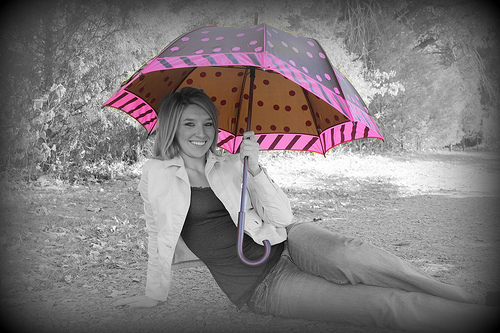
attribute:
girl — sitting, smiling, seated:
[128, 86, 499, 332]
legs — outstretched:
[247, 222, 498, 332]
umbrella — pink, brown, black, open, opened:
[99, 14, 386, 266]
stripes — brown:
[275, 132, 296, 149]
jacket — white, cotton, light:
[132, 148, 305, 291]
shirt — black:
[169, 157, 278, 309]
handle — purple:
[227, 209, 277, 269]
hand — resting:
[106, 293, 166, 309]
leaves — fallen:
[34, 202, 152, 300]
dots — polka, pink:
[287, 43, 316, 77]